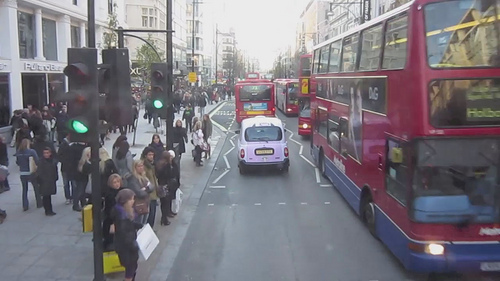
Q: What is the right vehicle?
A: Autobus.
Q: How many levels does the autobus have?
A: 2.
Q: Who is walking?
A: Pedestrians.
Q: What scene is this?
A: City street.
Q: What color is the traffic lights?
A: Green.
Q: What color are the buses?
A: Red.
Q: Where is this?
A: Outside in city.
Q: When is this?
A: During the day time.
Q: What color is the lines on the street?
A: White.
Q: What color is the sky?
A: Gray.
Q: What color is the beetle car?
A: Purple.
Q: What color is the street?
A: Gray.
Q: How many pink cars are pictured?
A: One.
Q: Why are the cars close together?
A: Heavily trafficked.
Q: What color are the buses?
A: Red and blue.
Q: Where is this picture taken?
A: Street of a city.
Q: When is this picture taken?
A: During rush hour.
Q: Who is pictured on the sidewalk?
A: Shoppers.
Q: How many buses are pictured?
A: Three.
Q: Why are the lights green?
A: Indicating to go.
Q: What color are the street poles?
A: Black.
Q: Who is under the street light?
A: A woman.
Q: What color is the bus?
A: Red and blue.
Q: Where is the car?
A: Next to the bus.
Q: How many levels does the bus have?
A: Two.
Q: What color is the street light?
A: Green.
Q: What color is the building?
A: White.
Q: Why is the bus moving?
A: The light is green.